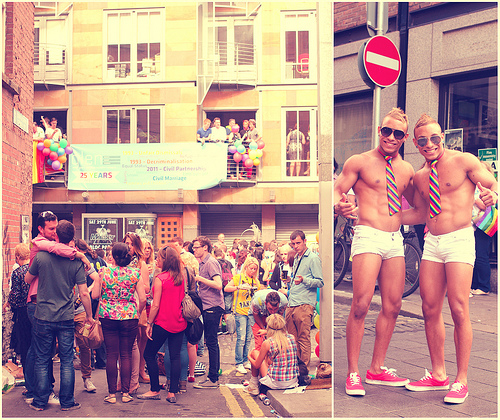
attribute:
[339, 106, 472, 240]
men — shirtless, happy, happpy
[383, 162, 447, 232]
neckties — colorful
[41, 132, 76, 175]
balloons — colorful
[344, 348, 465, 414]
shoes — red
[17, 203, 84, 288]
couples — hugging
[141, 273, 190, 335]
shirt — red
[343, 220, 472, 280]
shorts — white, short